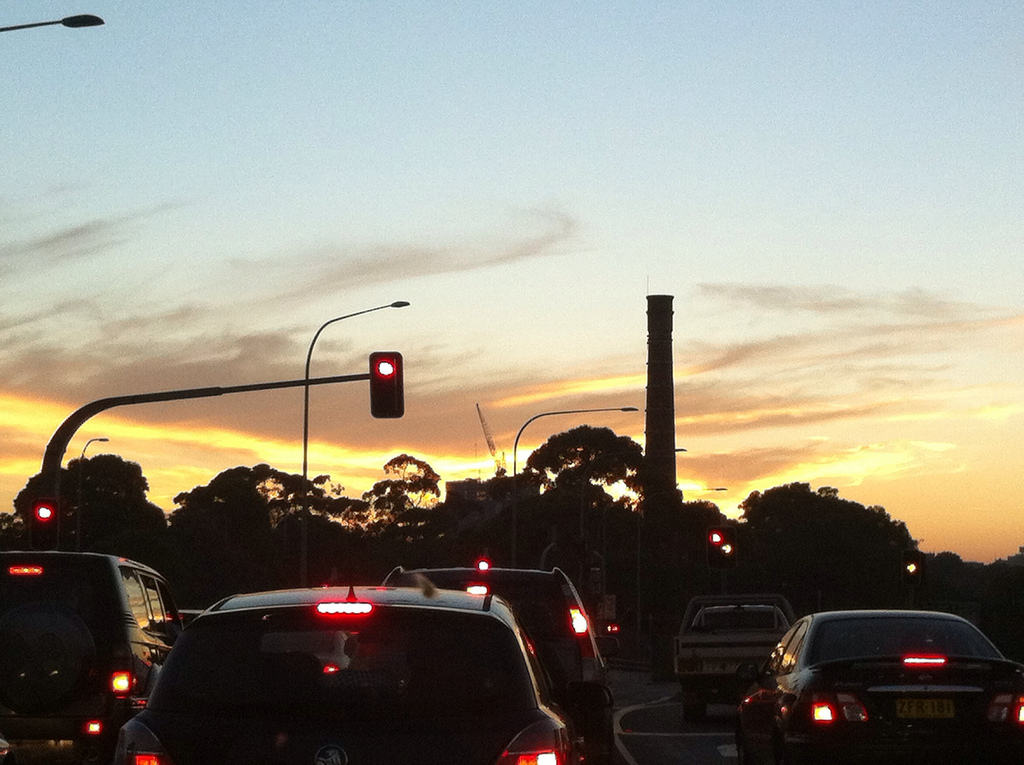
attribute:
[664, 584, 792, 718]
truck — white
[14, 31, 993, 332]
sky — blue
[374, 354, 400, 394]
light — red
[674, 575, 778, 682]
truck — pickup, turning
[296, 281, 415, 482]
light pole — tall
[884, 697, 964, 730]
plate — yellow 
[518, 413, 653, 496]
tree — distance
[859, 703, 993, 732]
plate — license 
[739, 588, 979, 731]
car — black 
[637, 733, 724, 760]
road — black suv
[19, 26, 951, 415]
clouds — sky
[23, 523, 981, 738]
cars — road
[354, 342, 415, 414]
signal light — post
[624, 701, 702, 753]
lines — road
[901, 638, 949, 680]
light — red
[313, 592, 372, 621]
light — red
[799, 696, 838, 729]
light — red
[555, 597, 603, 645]
light — red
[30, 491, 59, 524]
light — red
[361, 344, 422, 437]
light — traffic, red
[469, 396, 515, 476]
crane — contruction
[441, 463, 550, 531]
building — distant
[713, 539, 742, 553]
arrow — traffic, white, lit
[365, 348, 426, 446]
light — traffic